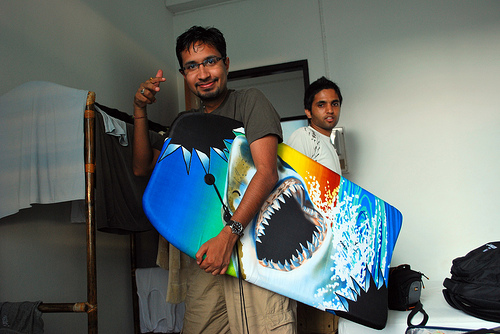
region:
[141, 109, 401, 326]
board featuring a picture of a sharkk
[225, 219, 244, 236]
black and silver watch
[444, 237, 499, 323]
black bookbag with white lettering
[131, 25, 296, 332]
man in grey shirt gesturing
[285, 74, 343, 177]
man in white shirt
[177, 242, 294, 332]
khaki pants or shorts being worn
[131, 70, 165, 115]
hand with a ring on the ring finger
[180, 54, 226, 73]
dark rimmed glasses being worn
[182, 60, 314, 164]
window behind two men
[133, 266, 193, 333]
white a-shirt hanging over something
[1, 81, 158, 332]
A bunk bed made of wood.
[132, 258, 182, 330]
An undershirt hanging on the rail of the bunk bed.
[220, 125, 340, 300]
The image of a shark.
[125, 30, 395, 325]
Man holding a surfboard.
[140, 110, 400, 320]
A colorful surfboard design.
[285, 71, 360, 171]
A man in a white tee shirt.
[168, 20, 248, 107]
Man with clear eyeglasses.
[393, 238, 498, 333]
Pieces of luggage on a bed.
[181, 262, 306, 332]
Man wearing tan cargo pants.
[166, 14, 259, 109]
Man with moustache and beard.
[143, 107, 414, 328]
a small body board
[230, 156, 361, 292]
a shark on a board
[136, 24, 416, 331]
a man carrying a body board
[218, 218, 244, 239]
a watch on a left arm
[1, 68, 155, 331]
a set of bunk beds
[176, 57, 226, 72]
glasses on a man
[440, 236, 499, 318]
a black back pack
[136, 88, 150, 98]
a ring on a finger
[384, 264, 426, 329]
a small black case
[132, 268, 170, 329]
a shirt on a rail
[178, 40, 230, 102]
this is his face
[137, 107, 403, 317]
this is a surf board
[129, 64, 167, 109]
this is his hand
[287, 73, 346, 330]
this is a man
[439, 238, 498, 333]
this is a black bag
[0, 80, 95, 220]
this is a white t-shirt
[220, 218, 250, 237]
this is a watch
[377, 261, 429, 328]
this is a small bag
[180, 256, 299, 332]
these are his khaki pants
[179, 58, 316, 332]
this is the doorway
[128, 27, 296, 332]
man holding a surfboard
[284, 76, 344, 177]
man wearing white t-shirt behind surfboard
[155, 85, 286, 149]
gray t-shirt of man holding a surfboard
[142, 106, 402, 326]
blue surfboard with a shark on it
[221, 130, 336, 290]
white shark on a surfboard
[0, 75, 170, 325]
wooden bunk bed on a bedroom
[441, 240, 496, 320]
black bagpack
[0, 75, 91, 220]
blue and white bathtowel hanging in the bunk bed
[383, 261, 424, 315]
black lunch box on white counter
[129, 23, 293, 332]
man with glasses holding shark surfboard